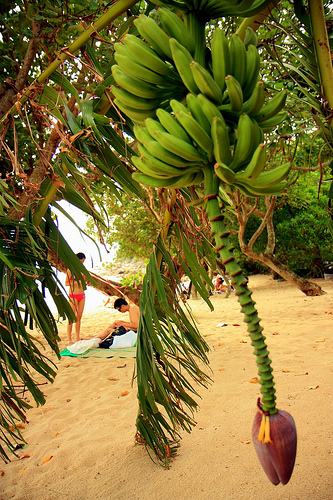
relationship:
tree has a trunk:
[84, 145, 326, 296] [245, 247, 323, 295]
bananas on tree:
[186, 69, 260, 151] [0, 2, 296, 486]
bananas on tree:
[229, 113, 254, 169] [300, 6, 331, 135]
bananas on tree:
[229, 113, 254, 169] [0, 2, 126, 223]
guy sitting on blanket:
[95, 298, 139, 349] [62, 324, 151, 354]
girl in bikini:
[65, 252, 86, 344] [68, 294, 85, 303]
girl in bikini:
[65, 252, 86, 344] [69, 274, 86, 280]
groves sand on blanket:
[0, 275, 333, 498] [57, 340, 140, 362]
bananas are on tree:
[229, 113, 254, 169] [1, 5, 332, 485]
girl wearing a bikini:
[65, 252, 86, 344] [62, 270, 93, 302]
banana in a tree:
[235, 160, 292, 189] [100, 4, 299, 486]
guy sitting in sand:
[95, 298, 139, 349] [0, 269, 331, 498]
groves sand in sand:
[54, 370, 128, 448] [0, 269, 331, 498]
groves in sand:
[219, 354, 240, 477] [0, 269, 331, 498]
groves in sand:
[282, 367, 291, 374] [0, 269, 331, 498]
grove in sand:
[64, 396, 75, 407] [0, 269, 331, 498]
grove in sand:
[111, 359, 128, 369] [0, 269, 331, 498]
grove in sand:
[60, 363, 71, 370] [0, 269, 331, 498]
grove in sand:
[114, 386, 130, 401] [0, 269, 331, 498]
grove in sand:
[211, 333, 228, 348] [0, 269, 331, 498]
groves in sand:
[250, 376, 259, 384] [0, 269, 331, 498]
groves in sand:
[272, 330, 280, 335] [0, 269, 331, 498]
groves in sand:
[40, 453, 53, 464] [0, 269, 331, 498]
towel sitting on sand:
[65, 337, 102, 355] [0, 269, 331, 498]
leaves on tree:
[59, 89, 119, 170] [287, 1, 321, 140]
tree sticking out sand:
[211, 124, 327, 305] [16, 274, 330, 457]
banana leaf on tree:
[131, 187, 219, 471] [1, 5, 332, 485]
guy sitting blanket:
[95, 298, 139, 349] [58, 323, 184, 365]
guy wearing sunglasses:
[86, 307, 141, 356] [116, 304, 127, 315]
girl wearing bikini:
[58, 256, 85, 338] [68, 291, 85, 300]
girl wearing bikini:
[65, 252, 86, 344] [69, 274, 85, 280]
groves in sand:
[46, 405, 142, 490] [43, 388, 129, 428]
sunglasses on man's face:
[114, 308, 123, 312] [115, 303, 126, 312]